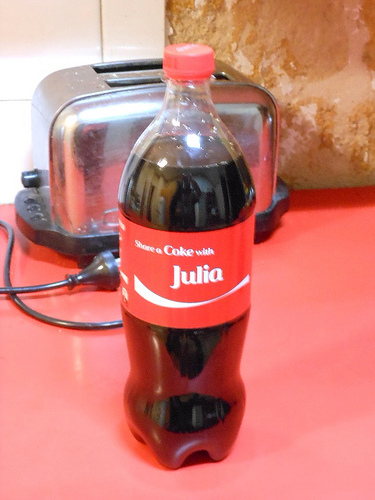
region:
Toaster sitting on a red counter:
[1, 55, 290, 334]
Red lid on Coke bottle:
[160, 44, 216, 79]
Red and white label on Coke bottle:
[117, 210, 255, 332]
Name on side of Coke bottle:
[117, 205, 255, 331]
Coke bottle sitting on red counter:
[117, 41, 254, 467]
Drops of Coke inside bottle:
[115, 78, 265, 171]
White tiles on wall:
[1, 2, 165, 205]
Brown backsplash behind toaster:
[166, 1, 373, 191]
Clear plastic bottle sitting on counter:
[112, 43, 266, 471]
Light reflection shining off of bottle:
[183, 126, 204, 155]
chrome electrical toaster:
[11, 51, 290, 272]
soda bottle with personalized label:
[116, 38, 262, 475]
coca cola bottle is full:
[109, 40, 257, 472]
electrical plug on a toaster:
[59, 246, 120, 295]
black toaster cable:
[1, 215, 123, 333]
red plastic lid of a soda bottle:
[160, 38, 216, 83]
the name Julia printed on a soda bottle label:
[166, 262, 224, 293]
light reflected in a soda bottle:
[176, 125, 208, 157]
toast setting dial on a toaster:
[19, 167, 42, 190]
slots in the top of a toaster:
[92, 53, 233, 94]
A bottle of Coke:
[113, 36, 260, 476]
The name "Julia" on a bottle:
[167, 259, 224, 293]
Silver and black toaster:
[13, 48, 286, 268]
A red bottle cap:
[156, 34, 217, 89]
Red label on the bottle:
[111, 208, 261, 332]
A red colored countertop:
[1, 182, 372, 497]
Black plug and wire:
[0, 214, 126, 338]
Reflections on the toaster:
[62, 104, 156, 227]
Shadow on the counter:
[280, 180, 373, 212]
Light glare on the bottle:
[177, 124, 209, 158]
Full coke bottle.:
[113, 41, 260, 469]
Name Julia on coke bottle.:
[165, 262, 228, 291]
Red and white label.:
[114, 209, 254, 331]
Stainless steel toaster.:
[11, 56, 291, 243]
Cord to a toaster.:
[0, 214, 122, 333]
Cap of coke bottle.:
[163, 43, 214, 83]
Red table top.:
[255, 239, 374, 498]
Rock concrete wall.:
[277, 2, 372, 190]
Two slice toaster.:
[13, 56, 299, 260]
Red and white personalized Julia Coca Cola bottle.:
[113, 42, 257, 471]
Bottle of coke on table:
[123, 44, 259, 462]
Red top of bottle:
[162, 39, 214, 77]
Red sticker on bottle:
[117, 216, 257, 332]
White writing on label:
[130, 240, 248, 308]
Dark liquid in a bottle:
[118, 155, 257, 232]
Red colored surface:
[0, 189, 372, 498]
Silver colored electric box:
[20, 63, 298, 244]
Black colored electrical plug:
[63, 249, 125, 291]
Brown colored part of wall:
[168, 2, 373, 185]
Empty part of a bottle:
[134, 87, 237, 162]